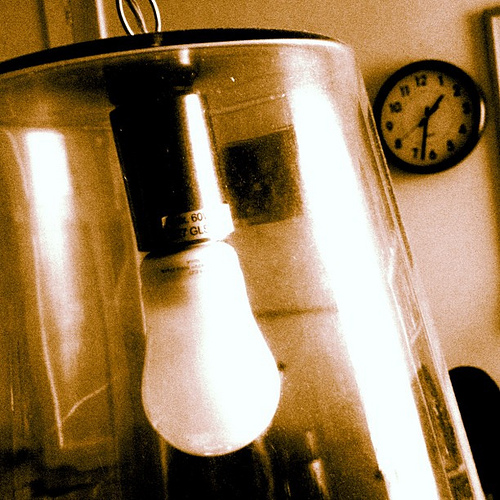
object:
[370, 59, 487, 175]
clock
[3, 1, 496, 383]
wall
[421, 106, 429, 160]
minute hand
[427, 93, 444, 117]
hour hand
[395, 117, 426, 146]
second hand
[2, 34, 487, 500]
container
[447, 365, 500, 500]
object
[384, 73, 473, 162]
numbers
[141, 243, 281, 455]
light bulb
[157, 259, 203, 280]
label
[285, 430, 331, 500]
vase